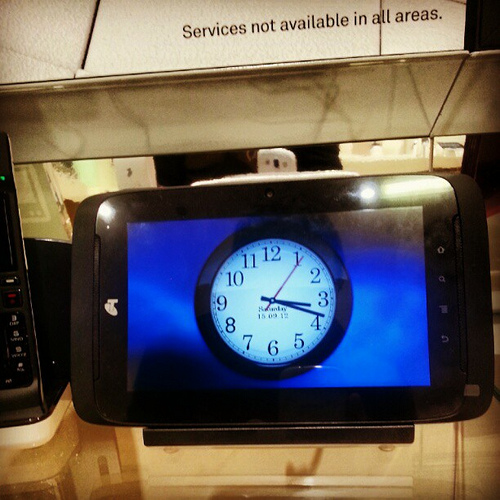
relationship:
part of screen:
[386, 328, 399, 343] [128, 205, 430, 390]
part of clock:
[267, 327, 314, 408] [189, 220, 364, 384]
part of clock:
[267, 327, 304, 365] [197, 222, 354, 378]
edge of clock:
[275, 360, 314, 375] [189, 220, 364, 384]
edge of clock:
[286, 365, 323, 384] [189, 220, 364, 384]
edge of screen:
[69, 170, 493, 427] [128, 205, 430, 390]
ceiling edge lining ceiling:
[2, 42, 497, 100] [2, 45, 484, 164]